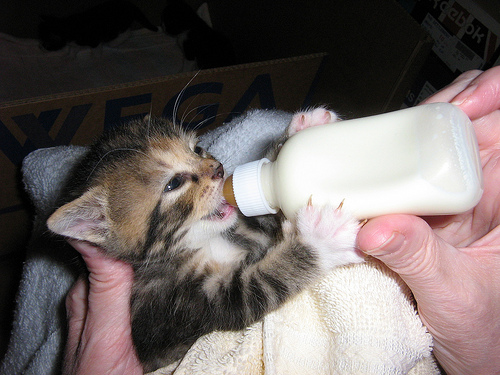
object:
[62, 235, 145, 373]
hand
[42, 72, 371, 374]
kitten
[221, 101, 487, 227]
bottle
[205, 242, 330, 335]
leg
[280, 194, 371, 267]
paw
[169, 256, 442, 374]
blanket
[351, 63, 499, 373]
hand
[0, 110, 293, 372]
towel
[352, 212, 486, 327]
thumb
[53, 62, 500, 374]
person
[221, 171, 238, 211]
nipple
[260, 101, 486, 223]
milk